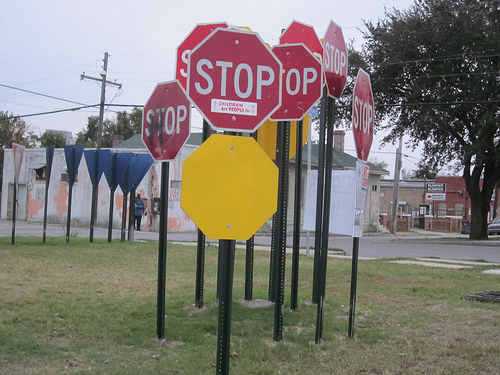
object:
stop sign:
[186, 26, 283, 132]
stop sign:
[141, 80, 193, 161]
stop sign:
[268, 43, 324, 121]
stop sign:
[321, 19, 350, 100]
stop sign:
[351, 67, 378, 161]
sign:
[180, 133, 280, 239]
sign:
[62, 143, 85, 179]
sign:
[82, 148, 110, 185]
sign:
[108, 151, 132, 192]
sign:
[125, 152, 156, 194]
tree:
[308, 0, 496, 240]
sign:
[12, 143, 29, 184]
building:
[1, 134, 195, 233]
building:
[120, 129, 389, 237]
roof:
[114, 132, 387, 173]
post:
[154, 160, 172, 339]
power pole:
[81, 51, 122, 223]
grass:
[1, 237, 499, 375]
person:
[131, 190, 147, 231]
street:
[1, 217, 500, 267]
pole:
[315, 96, 336, 342]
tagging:
[150, 110, 164, 145]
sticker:
[210, 98, 258, 118]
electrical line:
[0, 104, 101, 121]